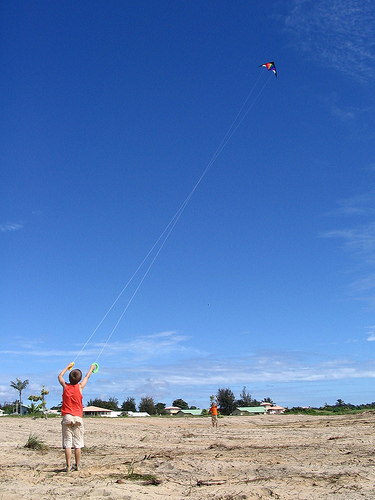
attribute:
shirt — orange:
[63, 388, 81, 413]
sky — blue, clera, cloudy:
[254, 51, 288, 92]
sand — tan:
[261, 435, 315, 472]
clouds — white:
[147, 341, 169, 358]